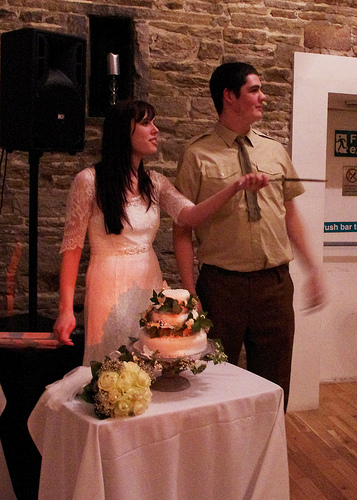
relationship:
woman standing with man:
[57, 100, 203, 323] [172, 60, 327, 415]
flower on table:
[81, 358, 151, 422] [25, 360, 289, 498]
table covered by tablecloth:
[51, 391, 323, 478] [23, 346, 293, 497]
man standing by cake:
[172, 60, 327, 415] [128, 280, 214, 359]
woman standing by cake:
[50, 98, 271, 369] [128, 280, 214, 359]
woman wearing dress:
[50, 98, 271, 369] [56, 161, 195, 366]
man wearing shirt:
[172, 60, 327, 415] [173, 118, 304, 271]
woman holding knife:
[50, 98, 271, 369] [264, 174, 330, 184]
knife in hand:
[264, 174, 330, 184] [228, 164, 271, 194]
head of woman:
[108, 102, 184, 165] [44, 102, 188, 347]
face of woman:
[128, 104, 163, 156] [50, 98, 271, 369]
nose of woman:
[149, 123, 158, 134] [44, 97, 193, 374]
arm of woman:
[25, 170, 114, 365] [50, 98, 271, 369]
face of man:
[211, 66, 270, 126] [172, 60, 327, 415]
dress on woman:
[56, 161, 195, 366] [50, 98, 271, 369]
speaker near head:
[2, 22, 93, 163] [101, 98, 160, 156]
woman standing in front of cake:
[50, 98, 271, 369] [138, 288, 213, 383]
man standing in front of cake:
[172, 60, 327, 415] [138, 288, 213, 383]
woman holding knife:
[50, 98, 271, 369] [239, 165, 335, 193]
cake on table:
[131, 283, 216, 394] [27, 346, 291, 499]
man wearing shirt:
[172, 60, 331, 414] [173, 118, 304, 271]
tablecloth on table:
[23, 346, 293, 497] [45, 348, 286, 429]